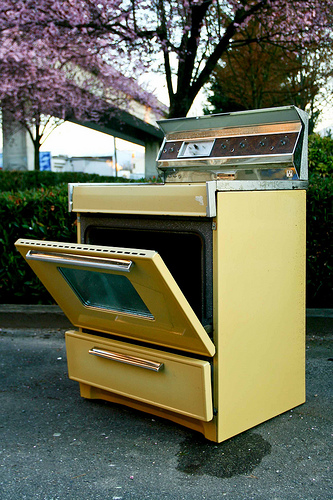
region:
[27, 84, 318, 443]
old yellow stove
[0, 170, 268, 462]
stove with its oven door open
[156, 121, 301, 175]
timer and knobs of a stove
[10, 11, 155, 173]
bright purple flowers on a tree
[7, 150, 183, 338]
green pruned bushes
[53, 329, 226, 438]
broiler pan with a silver handle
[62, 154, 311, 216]
silver stove top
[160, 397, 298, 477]
some liquid spilled on the ground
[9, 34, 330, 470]
stove sitting on a road outside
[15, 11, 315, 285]
trees and bushes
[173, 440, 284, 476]
wet spot on concrete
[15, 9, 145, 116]
beautiful purple blossoms on branch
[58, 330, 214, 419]
yellow bottom drawer on oven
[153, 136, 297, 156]
stovetop and oven dials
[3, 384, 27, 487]
white speckled grey asphalt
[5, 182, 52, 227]
dark green bushes and dying leaves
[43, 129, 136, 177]
window on side of building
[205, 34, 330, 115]
colorful leaves on tree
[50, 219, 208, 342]
half opened oven door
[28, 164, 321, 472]
big yellow oven on grey asphalt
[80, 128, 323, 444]
a yellow stove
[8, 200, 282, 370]
a stove with the oven door open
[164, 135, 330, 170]
a panel for the controls on the stove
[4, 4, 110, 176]
a tree with pink flowers growing on it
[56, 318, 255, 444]
a storage draw on a stove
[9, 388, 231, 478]
black pavement that the stove is sitting on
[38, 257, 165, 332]
glass window on oven door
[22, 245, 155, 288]
handle on oven door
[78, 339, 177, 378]
silver handle on storage draw on the oven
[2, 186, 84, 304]
bushes behind the stove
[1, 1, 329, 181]
Trees are in the background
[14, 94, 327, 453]
An oven in the foreground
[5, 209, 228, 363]
Oven door is open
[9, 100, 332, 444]
Oven is tan colored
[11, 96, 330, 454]
Oven is outside the house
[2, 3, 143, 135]
Trees have flowers blooming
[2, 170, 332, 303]
A green bush in the background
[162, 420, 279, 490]
Oven is leaking water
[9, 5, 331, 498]
Photo was taken in the daytime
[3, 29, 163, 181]
A building is in the background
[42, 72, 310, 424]
old yellow stove outside on pavement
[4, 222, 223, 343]
yellow oven door is open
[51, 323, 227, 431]
yellow broiler door is open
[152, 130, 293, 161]
oven control panel missing knobs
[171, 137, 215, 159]
damaged clock on control panel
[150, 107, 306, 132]
stove top light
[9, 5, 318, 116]
trees in the background with purple flowers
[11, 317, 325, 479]
yellow stove is outside on grey pavement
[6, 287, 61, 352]
curb is behind the stove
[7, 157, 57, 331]
bushes are behind the curb